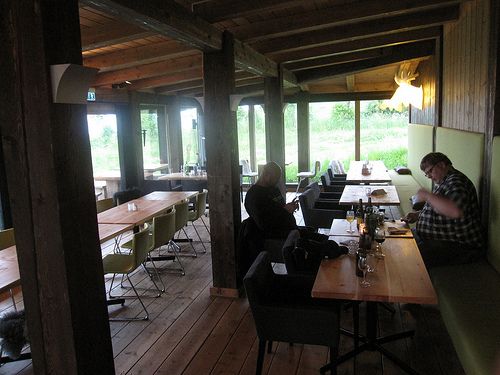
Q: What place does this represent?
A: It represents the patio.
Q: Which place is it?
A: It is a patio.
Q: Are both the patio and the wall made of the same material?
A: Yes, both the patio and the wall are made of wood.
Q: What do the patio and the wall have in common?
A: The material, both the patio and the wall are wooden.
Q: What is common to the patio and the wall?
A: The material, both the patio and the wall are wooden.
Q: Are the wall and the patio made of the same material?
A: Yes, both the wall and the patio are made of wood.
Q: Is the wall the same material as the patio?
A: Yes, both the wall and the patio are made of wood.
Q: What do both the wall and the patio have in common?
A: The material, both the wall and the patio are wooden.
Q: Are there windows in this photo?
A: Yes, there is a window.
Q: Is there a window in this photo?
A: Yes, there is a window.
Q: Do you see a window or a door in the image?
A: Yes, there is a window.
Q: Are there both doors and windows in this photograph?
A: No, there is a window but no doors.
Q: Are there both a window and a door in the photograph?
A: No, there is a window but no doors.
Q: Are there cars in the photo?
A: No, there are no cars.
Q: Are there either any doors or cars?
A: No, there are no cars or doors.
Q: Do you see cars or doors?
A: No, there are no cars or doors.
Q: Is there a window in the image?
A: Yes, there is a window.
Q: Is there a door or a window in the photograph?
A: Yes, there is a window.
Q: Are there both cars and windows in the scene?
A: No, there is a window but no cars.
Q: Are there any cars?
A: No, there are no cars.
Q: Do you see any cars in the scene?
A: No, there are no cars.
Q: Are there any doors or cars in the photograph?
A: No, there are no cars or doors.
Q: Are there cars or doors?
A: No, there are no cars or doors.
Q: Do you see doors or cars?
A: No, there are no cars or doors.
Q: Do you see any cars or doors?
A: No, there are no cars or doors.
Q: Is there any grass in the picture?
A: Yes, there is grass.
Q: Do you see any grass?
A: Yes, there is grass.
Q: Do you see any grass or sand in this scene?
A: Yes, there is grass.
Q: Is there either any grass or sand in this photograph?
A: Yes, there is grass.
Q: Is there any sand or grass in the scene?
A: Yes, there is grass.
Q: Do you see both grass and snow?
A: No, there is grass but no snow.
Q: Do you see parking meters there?
A: No, there are no parking meters.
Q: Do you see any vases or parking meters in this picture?
A: No, there are no parking meters or vases.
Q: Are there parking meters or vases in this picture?
A: No, there are no parking meters or vases.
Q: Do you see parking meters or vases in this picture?
A: No, there are no parking meters or vases.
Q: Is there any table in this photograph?
A: Yes, there is a table.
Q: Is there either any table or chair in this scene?
A: Yes, there is a table.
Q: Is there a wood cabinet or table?
A: Yes, there is a wood table.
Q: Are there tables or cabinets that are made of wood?
A: Yes, the table is made of wood.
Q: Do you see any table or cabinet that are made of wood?
A: Yes, the table is made of wood.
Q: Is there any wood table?
A: Yes, there is a table that is made of wood.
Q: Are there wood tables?
A: Yes, there is a table that is made of wood.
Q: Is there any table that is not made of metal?
A: Yes, there is a table that is made of wood.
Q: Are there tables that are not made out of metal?
A: Yes, there is a table that is made of wood.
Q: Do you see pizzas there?
A: No, there are no pizzas.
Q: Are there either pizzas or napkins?
A: No, there are no pizzas or napkins.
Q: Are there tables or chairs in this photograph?
A: Yes, there is a table.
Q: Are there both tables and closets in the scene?
A: No, there is a table but no closets.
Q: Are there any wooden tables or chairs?
A: Yes, there is a wood table.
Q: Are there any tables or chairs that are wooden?
A: Yes, the table is wooden.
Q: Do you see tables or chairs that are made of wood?
A: Yes, the table is made of wood.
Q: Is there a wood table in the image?
A: Yes, there is a wood table.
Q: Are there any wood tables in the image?
A: Yes, there is a wood table.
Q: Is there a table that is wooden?
A: Yes, there is a table that is wooden.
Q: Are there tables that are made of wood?
A: Yes, there is a table that is made of wood.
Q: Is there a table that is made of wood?
A: Yes, there is a table that is made of wood.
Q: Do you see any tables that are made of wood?
A: Yes, there is a table that is made of wood.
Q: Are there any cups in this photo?
A: No, there are no cups.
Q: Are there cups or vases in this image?
A: No, there are no cups or vases.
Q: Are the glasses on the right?
A: Yes, the glasses are on the right of the image.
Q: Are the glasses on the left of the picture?
A: No, the glasses are on the right of the image.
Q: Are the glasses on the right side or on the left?
A: The glasses are on the right of the image.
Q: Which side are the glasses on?
A: The glasses are on the right of the image.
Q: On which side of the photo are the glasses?
A: The glasses are on the right of the image.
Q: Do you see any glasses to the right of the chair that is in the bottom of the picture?
A: Yes, there are glasses to the right of the chair.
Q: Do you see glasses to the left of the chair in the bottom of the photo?
A: No, the glasses are to the right of the chair.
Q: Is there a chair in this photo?
A: Yes, there is a chair.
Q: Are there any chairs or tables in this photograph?
A: Yes, there is a chair.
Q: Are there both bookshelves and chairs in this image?
A: No, there is a chair but no bookshelves.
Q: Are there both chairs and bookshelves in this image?
A: No, there is a chair but no bookshelves.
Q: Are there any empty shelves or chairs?
A: Yes, there is an empty chair.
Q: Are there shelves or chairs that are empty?
A: Yes, the chair is empty.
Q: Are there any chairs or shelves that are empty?
A: Yes, the chair is empty.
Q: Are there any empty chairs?
A: Yes, there is an empty chair.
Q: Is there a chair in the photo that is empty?
A: Yes, there is a chair that is empty.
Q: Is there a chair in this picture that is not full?
A: Yes, there is a empty chair.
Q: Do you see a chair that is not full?
A: Yes, there is a empty chair.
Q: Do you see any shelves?
A: No, there are no shelves.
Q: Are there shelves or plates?
A: No, there are no shelves or plates.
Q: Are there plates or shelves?
A: No, there are no shelves or plates.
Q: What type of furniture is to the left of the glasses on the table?
A: The piece of furniture is a chair.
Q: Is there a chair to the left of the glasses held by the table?
A: Yes, there is a chair to the left of the glasses.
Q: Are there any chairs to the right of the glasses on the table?
A: No, the chair is to the left of the glasses.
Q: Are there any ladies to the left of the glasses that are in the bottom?
A: No, there is a chair to the left of the glasses.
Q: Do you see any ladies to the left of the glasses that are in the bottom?
A: No, there is a chair to the left of the glasses.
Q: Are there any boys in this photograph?
A: No, there are no boys.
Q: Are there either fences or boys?
A: No, there are no boys or fences.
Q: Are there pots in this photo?
A: No, there are no pots.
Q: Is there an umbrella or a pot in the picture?
A: No, there are no pots or umbrellas.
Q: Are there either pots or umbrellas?
A: No, there are no pots or umbrellas.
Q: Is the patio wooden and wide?
A: Yes, the patio is wooden and wide.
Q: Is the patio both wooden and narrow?
A: No, the patio is wooden but wide.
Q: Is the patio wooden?
A: Yes, the patio is wooden.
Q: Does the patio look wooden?
A: Yes, the patio is wooden.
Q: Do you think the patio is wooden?
A: Yes, the patio is wooden.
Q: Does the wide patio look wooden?
A: Yes, the patio is wooden.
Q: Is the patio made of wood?
A: Yes, the patio is made of wood.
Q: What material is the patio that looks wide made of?
A: The patio is made of wood.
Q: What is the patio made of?
A: The patio is made of wood.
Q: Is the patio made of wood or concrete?
A: The patio is made of wood.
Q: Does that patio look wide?
A: Yes, the patio is wide.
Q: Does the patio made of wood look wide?
A: Yes, the patio is wide.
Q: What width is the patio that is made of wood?
A: The patio is wide.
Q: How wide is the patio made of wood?
A: The patio is wide.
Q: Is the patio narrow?
A: No, the patio is wide.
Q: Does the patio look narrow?
A: No, the patio is wide.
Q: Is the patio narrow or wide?
A: The patio is wide.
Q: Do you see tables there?
A: Yes, there is a table.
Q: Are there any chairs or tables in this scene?
A: Yes, there is a table.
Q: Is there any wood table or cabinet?
A: Yes, there is a wood table.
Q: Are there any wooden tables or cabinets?
A: Yes, there is a wood table.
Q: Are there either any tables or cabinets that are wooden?
A: Yes, the table is wooden.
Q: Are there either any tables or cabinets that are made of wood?
A: Yes, the table is made of wood.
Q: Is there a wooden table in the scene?
A: Yes, there is a wood table.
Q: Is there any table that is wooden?
A: Yes, there is a table that is wooden.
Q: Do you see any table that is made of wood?
A: Yes, there is a table that is made of wood.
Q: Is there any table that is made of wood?
A: Yes, there is a table that is made of wood.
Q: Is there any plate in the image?
A: No, there are no plates.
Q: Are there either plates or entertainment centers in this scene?
A: No, there are no plates or entertainment centers.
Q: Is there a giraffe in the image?
A: No, there are no giraffes.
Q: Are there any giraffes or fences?
A: No, there are no giraffes or fences.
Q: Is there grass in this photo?
A: Yes, there is grass.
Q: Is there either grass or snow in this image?
A: Yes, there is grass.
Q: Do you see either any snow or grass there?
A: Yes, there is grass.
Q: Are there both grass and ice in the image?
A: No, there is grass but no ice.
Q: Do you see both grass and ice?
A: No, there is grass but no ice.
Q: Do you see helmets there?
A: No, there are no helmets.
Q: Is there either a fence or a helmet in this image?
A: No, there are no helmets or fences.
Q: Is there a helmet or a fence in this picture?
A: No, there are no helmets or fences.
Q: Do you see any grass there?
A: Yes, there is grass.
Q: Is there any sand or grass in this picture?
A: Yes, there is grass.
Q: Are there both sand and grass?
A: No, there is grass but no sand.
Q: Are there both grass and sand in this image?
A: No, there is grass but no sand.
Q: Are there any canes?
A: No, there are no canes.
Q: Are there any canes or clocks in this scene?
A: No, there are no canes or clocks.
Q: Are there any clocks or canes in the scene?
A: No, there are no canes or clocks.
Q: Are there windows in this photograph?
A: Yes, there is a window.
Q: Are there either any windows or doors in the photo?
A: Yes, there is a window.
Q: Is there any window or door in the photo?
A: Yes, there is a window.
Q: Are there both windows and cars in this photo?
A: No, there is a window but no cars.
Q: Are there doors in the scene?
A: No, there are no doors.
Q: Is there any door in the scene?
A: No, there are no doors.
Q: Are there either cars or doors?
A: No, there are no doors or cars.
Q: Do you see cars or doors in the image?
A: No, there are no doors or cars.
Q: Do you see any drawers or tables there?
A: Yes, there is a table.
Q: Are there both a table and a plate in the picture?
A: No, there is a table but no plates.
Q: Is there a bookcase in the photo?
A: No, there are no bookcases.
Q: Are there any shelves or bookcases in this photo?
A: No, there are no bookcases or shelves.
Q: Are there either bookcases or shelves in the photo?
A: No, there are no bookcases or shelves.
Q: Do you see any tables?
A: Yes, there is a table.